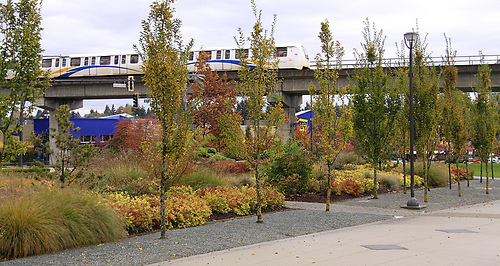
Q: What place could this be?
A: It is a sidewalk.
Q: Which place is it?
A: It is a sidewalk.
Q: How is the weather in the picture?
A: It is cloudy.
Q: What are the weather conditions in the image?
A: It is cloudy.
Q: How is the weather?
A: It is cloudy.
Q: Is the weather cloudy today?
A: Yes, it is cloudy.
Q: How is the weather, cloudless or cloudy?
A: It is cloudy.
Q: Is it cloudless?
A: No, it is cloudy.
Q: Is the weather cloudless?
A: No, it is cloudy.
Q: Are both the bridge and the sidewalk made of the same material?
A: Yes, both the bridge and the sidewalk are made of cement.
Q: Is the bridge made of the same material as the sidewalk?
A: Yes, both the bridge and the sidewalk are made of cement.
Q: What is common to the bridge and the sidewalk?
A: The material, both the bridge and the sidewalk are concrete.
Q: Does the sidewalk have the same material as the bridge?
A: Yes, both the sidewalk and the bridge are made of concrete.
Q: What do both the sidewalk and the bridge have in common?
A: The material, both the sidewalk and the bridge are concrete.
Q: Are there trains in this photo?
A: Yes, there is a train.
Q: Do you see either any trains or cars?
A: Yes, there is a train.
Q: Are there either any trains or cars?
A: Yes, there is a train.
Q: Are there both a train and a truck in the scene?
A: No, there is a train but no trucks.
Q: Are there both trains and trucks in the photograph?
A: No, there is a train but no trucks.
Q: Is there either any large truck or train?
A: Yes, there is a large train.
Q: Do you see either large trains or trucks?
A: Yes, there is a large train.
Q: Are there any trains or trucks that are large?
A: Yes, the train is large.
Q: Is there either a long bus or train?
A: Yes, there is a long train.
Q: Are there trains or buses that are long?
A: Yes, the train is long.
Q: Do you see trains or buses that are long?
A: Yes, the train is long.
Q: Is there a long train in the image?
A: Yes, there is a long train.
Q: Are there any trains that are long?
A: Yes, there is a train that is long.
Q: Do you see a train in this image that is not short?
A: Yes, there is a long train.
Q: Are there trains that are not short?
A: Yes, there is a long train.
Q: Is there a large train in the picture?
A: Yes, there is a large train.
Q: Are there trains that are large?
A: Yes, there is a train that is large.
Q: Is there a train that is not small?
A: Yes, there is a large train.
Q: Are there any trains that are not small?
A: Yes, there is a large train.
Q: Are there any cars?
A: No, there are no cars.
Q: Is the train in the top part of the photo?
A: Yes, the train is in the top of the image.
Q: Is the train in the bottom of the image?
A: No, the train is in the top of the image.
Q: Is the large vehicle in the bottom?
A: No, the train is in the top of the image.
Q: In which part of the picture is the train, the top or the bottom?
A: The train is in the top of the image.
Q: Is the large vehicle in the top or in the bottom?
A: The train is in the top of the image.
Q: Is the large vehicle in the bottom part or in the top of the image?
A: The train is in the top of the image.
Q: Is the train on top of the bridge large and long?
A: Yes, the train is large and long.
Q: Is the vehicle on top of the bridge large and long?
A: Yes, the train is large and long.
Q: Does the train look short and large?
A: No, the train is large but long.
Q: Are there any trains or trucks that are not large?
A: No, there is a train but it is large.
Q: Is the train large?
A: Yes, the train is large.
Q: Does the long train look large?
A: Yes, the train is large.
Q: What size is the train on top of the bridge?
A: The train is large.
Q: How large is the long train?
A: The train is large.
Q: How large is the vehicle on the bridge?
A: The train is large.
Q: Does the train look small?
A: No, the train is large.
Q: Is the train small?
A: No, the train is large.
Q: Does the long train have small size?
A: No, the train is large.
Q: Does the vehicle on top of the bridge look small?
A: No, the train is large.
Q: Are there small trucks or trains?
A: No, there is a train but it is large.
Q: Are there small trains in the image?
A: No, there is a train but it is large.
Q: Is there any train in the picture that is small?
A: No, there is a train but it is large.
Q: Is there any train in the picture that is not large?
A: No, there is a train but it is large.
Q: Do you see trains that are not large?
A: No, there is a train but it is large.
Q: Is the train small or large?
A: The train is large.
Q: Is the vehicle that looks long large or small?
A: The train is large.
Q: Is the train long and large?
A: Yes, the train is long and large.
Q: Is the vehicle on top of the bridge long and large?
A: Yes, the train is long and large.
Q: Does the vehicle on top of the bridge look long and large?
A: Yes, the train is long and large.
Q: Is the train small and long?
A: No, the train is long but large.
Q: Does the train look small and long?
A: No, the train is long but large.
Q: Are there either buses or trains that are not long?
A: No, there is a train but it is long.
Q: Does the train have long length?
A: Yes, the train is long.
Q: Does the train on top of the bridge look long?
A: Yes, the train is long.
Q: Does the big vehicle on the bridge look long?
A: Yes, the train is long.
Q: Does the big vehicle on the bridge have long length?
A: Yes, the train is long.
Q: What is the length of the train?
A: The train is long.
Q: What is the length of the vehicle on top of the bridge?
A: The train is long.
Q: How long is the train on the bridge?
A: The train is long.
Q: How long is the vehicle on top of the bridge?
A: The train is long.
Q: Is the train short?
A: No, the train is long.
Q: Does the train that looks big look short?
A: No, the train is long.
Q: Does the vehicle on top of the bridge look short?
A: No, the train is long.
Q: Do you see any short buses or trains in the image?
A: No, there is a train but it is long.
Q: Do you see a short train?
A: No, there is a train but it is long.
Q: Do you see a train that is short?
A: No, there is a train but it is long.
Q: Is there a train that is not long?
A: No, there is a train but it is long.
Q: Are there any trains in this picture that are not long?
A: No, there is a train but it is long.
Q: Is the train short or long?
A: The train is long.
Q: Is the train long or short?
A: The train is long.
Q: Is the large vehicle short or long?
A: The train is long.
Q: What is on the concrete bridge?
A: The train is on the bridge.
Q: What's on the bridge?
A: The train is on the bridge.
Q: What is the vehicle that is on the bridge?
A: The vehicle is a train.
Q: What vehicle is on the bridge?
A: The vehicle is a train.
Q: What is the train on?
A: The train is on the bridge.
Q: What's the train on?
A: The train is on the bridge.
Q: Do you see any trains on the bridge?
A: Yes, there is a train on the bridge.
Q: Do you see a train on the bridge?
A: Yes, there is a train on the bridge.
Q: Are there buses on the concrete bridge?
A: No, there is a train on the bridge.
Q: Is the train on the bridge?
A: Yes, the train is on the bridge.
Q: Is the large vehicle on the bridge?
A: Yes, the train is on the bridge.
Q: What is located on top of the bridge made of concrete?
A: The train is on top of the bridge.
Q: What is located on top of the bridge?
A: The train is on top of the bridge.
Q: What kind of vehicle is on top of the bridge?
A: The vehicle is a train.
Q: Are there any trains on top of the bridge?
A: Yes, there is a train on top of the bridge.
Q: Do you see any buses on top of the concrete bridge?
A: No, there is a train on top of the bridge.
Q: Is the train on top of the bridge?
A: Yes, the train is on top of the bridge.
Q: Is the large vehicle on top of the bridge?
A: Yes, the train is on top of the bridge.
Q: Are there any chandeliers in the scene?
A: No, there are no chandeliers.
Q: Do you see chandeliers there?
A: No, there are no chandeliers.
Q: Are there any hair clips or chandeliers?
A: No, there are no chandeliers or hair clips.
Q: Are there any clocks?
A: No, there are no clocks.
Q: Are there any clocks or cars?
A: No, there are no clocks or cars.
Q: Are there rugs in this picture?
A: No, there are no rugs.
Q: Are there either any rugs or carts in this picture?
A: No, there are no rugs or carts.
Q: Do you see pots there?
A: No, there are no pots.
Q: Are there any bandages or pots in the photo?
A: No, there are no pots or bandages.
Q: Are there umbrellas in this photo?
A: No, there are no umbrellas.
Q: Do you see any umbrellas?
A: No, there are no umbrellas.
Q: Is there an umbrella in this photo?
A: No, there are no umbrellas.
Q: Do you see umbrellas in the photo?
A: No, there are no umbrellas.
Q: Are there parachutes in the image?
A: No, there are no parachutes.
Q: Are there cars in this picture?
A: No, there are no cars.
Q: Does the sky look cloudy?
A: Yes, the sky is cloudy.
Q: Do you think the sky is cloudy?
A: Yes, the sky is cloudy.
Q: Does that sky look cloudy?
A: Yes, the sky is cloudy.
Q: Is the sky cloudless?
A: No, the sky is cloudy.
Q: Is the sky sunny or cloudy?
A: The sky is cloudy.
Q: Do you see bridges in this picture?
A: Yes, there is a bridge.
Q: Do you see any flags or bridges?
A: Yes, there is a bridge.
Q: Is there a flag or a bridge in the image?
A: Yes, there is a bridge.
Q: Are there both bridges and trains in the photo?
A: Yes, there are both a bridge and a train.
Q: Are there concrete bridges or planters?
A: Yes, there is a concrete bridge.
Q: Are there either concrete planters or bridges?
A: Yes, there is a concrete bridge.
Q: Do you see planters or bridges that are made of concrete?
A: Yes, the bridge is made of concrete.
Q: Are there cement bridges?
A: Yes, there is a bridge that is made of cement.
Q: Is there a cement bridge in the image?
A: Yes, there is a bridge that is made of cement.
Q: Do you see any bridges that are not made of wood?
A: Yes, there is a bridge that is made of concrete.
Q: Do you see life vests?
A: No, there are no life vests.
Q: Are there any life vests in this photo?
A: No, there are no life vests.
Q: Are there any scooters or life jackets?
A: No, there are no life jackets or scooters.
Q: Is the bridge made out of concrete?
A: Yes, the bridge is made of concrete.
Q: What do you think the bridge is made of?
A: The bridge is made of concrete.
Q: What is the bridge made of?
A: The bridge is made of concrete.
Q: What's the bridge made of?
A: The bridge is made of concrete.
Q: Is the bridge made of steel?
A: No, the bridge is made of cement.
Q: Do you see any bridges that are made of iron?
A: No, there is a bridge but it is made of cement.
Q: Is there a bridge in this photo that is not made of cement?
A: No, there is a bridge but it is made of cement.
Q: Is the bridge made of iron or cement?
A: The bridge is made of cement.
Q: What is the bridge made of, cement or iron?
A: The bridge is made of cement.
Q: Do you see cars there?
A: No, there are no cars.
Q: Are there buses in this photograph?
A: No, there are no buses.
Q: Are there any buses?
A: No, there are no buses.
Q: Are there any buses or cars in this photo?
A: No, there are no buses or cars.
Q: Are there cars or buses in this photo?
A: No, there are no buses or cars.